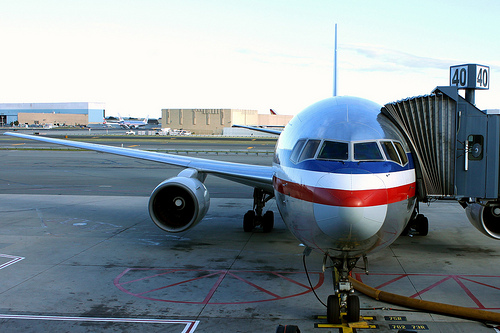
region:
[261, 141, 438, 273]
the plane has stripes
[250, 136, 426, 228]
the stripes are red, white, and blue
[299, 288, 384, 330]
two wheels on the front of the plane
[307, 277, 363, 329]
the wheels are black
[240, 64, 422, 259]
the plane is grey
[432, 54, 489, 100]
the numbers are black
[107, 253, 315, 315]
red symbol on the ground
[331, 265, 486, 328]
a pipe on the ground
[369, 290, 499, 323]
the pipe is tannish brown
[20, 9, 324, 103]
the sky is overcast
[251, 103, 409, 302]
this is a plane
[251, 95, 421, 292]
the plane is parked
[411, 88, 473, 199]
the door is open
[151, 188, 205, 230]
this is the propeller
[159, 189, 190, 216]
the inner is dark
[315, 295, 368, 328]
these are the wheels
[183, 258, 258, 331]
this is the runway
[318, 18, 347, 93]
this is the tail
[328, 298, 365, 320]
the wheels are black in color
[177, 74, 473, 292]
a plane docked at a terminal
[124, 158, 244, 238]
white engine of the plane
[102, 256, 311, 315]
red lines on the tarmac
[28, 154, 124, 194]
black tarmac of the airport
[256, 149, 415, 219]
red, white, and blue stripe on the plane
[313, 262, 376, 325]
front landing gear of the plane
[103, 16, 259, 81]
white cloudy skies over the airport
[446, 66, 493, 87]
black numbers on a white sign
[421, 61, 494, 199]
a skybridge docked to a plane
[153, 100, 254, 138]
a tan building in the background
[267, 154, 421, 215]
red, blue, and white stripes on plane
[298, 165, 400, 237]
gray nose of airplane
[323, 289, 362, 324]
two wheels on front of airplane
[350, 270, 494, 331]
yellow hose connected to airplane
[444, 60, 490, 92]
white background with black numbers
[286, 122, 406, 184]
cockpit of gray airplane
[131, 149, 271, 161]
silver railing along tarmac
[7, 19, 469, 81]
bright blue skies above airplane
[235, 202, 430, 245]
two sets of wheels on plane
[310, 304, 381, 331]
yellow lines with black outline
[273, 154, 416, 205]
white and red strips on airplane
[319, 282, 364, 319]
front wheels of airplae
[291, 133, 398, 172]
front windows of airplane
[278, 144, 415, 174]
blue stripe around front windows of airplane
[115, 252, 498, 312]
red lines painted on tarmac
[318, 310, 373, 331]
yellow lines painted on tarmac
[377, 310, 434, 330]
yellow lettering on black background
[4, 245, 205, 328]
white lines painted on tarmac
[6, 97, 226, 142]
buildings in the background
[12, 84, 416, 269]
silver airplane sitting on tarmac